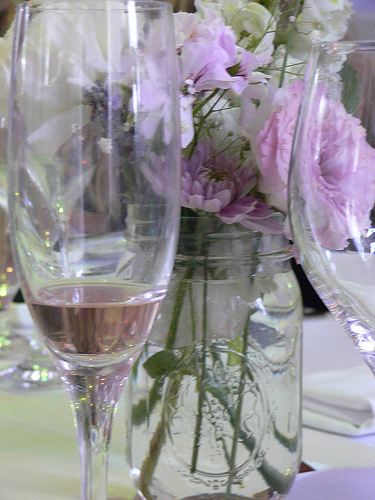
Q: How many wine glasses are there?
A: Three.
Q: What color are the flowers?
A: White and purple.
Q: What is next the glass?
A: Bottle filled with water.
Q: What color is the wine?
A: Purple.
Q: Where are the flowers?
A: Arranged in the bottle.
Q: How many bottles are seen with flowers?
A: One bottle.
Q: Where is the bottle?
A: On the table.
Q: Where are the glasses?
A: In the table.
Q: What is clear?
A: The glass.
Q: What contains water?
A: The glass.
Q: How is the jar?
A: It is clear.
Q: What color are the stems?
A: Green.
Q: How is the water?
A: Clear.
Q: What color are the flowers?
A: Lavender.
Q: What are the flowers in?
A: A mason jar.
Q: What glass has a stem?
A: A champagne flute.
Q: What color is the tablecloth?
A: White.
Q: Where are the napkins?
A: On the table.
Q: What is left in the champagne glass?
A: Champagne.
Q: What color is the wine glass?
A: Clear.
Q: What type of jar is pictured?
A: Glass.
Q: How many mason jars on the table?
A: One.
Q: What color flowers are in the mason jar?
A: Purple and white.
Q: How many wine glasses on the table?
A: Two.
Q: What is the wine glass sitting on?
A: A table.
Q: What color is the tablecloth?
A: White.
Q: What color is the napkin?
A: White.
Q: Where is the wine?
A: In a wine glass.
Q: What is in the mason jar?
A: Flowers.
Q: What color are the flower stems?
A: Green.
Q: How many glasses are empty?
A: One.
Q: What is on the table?
A: Glasses.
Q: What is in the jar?
A: Flowers.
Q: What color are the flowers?
A: Purple.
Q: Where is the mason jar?
A: On a table.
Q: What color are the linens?
A: White.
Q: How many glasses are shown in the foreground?
A: Two.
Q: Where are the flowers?
A: In the mason jar.